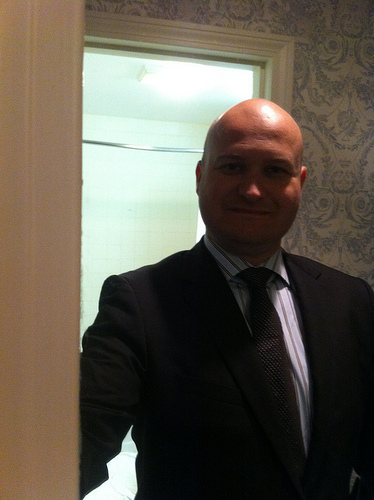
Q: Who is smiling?
A: The man is.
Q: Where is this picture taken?
A: Inside a building.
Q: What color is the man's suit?
A: Black.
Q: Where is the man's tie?
A: Around his neck.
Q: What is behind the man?
A: A window.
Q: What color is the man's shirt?
A: White striped.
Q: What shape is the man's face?
A: Oval.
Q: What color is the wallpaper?
A: White and grey.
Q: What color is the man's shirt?
A: Grey and white.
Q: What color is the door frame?
A: White.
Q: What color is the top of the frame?
A: White.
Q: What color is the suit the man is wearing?
A: Black.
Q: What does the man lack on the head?
A: Hair.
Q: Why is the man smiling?
A: Happy.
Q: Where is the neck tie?
A: Around the neck.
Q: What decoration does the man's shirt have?
A: Stripes.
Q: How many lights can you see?
A: 1.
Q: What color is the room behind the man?
A: Off white.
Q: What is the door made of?
A: Wood.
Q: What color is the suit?
A: Black.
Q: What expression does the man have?
A: A happy face.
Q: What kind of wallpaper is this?
A: Printed.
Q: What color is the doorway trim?
A: White.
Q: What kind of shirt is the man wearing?
A: Striped.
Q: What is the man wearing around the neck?
A: A tie.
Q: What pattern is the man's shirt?
A: Striped.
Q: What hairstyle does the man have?
A: The man is bald.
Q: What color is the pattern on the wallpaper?
A: Blue.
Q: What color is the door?
A: White.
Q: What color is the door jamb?
A: White.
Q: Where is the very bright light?
A: Behind the man.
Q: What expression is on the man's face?
A: The man is smiling.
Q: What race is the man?
A: Caucasian.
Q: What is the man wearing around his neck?
A: Tie.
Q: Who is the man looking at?
A: The photographer.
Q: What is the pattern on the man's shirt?
A: Striped.